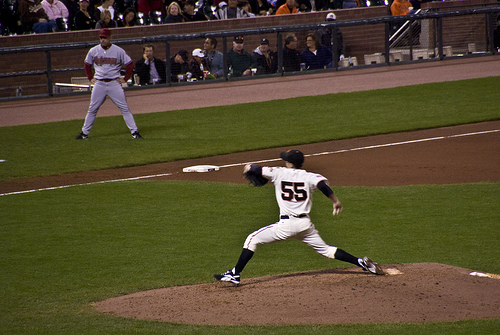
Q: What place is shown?
A: It is a field.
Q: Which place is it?
A: It is a field.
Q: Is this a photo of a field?
A: Yes, it is showing a field.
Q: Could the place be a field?
A: Yes, it is a field.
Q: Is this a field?
A: Yes, it is a field.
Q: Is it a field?
A: Yes, it is a field.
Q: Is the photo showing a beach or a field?
A: It is showing a field.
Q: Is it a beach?
A: No, it is a field.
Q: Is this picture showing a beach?
A: No, the picture is showing a field.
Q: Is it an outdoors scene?
A: Yes, it is outdoors.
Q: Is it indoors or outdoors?
A: It is outdoors.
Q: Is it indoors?
A: No, it is outdoors.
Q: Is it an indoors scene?
A: No, it is outdoors.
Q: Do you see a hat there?
A: Yes, there is a hat.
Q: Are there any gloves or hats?
A: Yes, there is a hat.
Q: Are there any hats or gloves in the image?
A: Yes, there is a hat.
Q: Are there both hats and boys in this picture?
A: No, there is a hat but no boys.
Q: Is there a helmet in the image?
A: No, there are no helmets.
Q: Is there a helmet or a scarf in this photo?
A: No, there are no helmets or scarves.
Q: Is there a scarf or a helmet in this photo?
A: No, there are no helmets or scarves.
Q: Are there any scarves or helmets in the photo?
A: No, there are no helmets or scarves.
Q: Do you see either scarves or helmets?
A: No, there are no helmets or scarves.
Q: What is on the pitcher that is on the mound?
A: The hat is on the pitcher.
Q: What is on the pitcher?
A: The hat is on the pitcher.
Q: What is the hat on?
A: The hat is on the pitcher.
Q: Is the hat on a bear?
A: No, the hat is on the pitcher.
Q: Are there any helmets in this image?
A: No, there are no helmets.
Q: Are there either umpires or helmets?
A: No, there are no helmets or umpires.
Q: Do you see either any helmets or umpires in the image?
A: No, there are no helmets or umpires.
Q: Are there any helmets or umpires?
A: No, there are no helmets or umpires.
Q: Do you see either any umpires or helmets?
A: No, there are no helmets or umpires.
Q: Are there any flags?
A: No, there are no flags.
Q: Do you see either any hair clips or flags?
A: No, there are no flags or hair clips.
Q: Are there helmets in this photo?
A: No, there are no helmets.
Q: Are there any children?
A: No, there are no children.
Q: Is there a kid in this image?
A: No, there are no children.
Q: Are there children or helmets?
A: No, there are no children or helmets.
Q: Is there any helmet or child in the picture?
A: No, there are no children or helmets.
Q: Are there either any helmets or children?
A: No, there are no children or helmets.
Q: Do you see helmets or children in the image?
A: No, there are no children or helmets.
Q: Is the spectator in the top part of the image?
A: Yes, the spectator is in the top of the image.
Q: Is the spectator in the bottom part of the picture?
A: No, the spectator is in the top of the image.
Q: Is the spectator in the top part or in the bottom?
A: The spectator is in the top of the image.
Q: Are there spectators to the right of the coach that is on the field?
A: Yes, there is a spectator to the right of the coach.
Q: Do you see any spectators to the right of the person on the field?
A: Yes, there is a spectator to the right of the coach.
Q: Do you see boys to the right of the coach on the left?
A: No, there is a spectator to the right of the coach.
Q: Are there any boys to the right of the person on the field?
A: No, there is a spectator to the right of the coach.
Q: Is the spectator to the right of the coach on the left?
A: Yes, the spectator is to the right of the coach.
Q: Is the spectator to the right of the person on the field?
A: Yes, the spectator is to the right of the coach.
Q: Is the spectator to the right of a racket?
A: No, the spectator is to the right of the coach.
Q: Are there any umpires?
A: No, there are no umpires.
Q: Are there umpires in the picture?
A: No, there are no umpires.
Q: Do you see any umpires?
A: No, there are no umpires.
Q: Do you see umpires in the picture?
A: No, there are no umpires.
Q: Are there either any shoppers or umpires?
A: No, there are no umpires or shoppers.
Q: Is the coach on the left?
A: Yes, the coach is on the left of the image.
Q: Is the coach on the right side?
A: No, the coach is on the left of the image.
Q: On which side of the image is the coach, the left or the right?
A: The coach is on the left of the image.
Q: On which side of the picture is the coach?
A: The coach is on the left of the image.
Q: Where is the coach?
A: The coach is on the field.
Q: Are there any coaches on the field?
A: Yes, there is a coach on the field.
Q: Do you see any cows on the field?
A: No, there is a coach on the field.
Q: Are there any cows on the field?
A: No, there is a coach on the field.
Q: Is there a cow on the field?
A: No, there is a coach on the field.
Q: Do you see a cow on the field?
A: No, there is a coach on the field.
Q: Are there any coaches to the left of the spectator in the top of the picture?
A: Yes, there is a coach to the left of the spectator.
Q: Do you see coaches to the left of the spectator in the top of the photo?
A: Yes, there is a coach to the left of the spectator.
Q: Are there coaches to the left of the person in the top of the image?
A: Yes, there is a coach to the left of the spectator.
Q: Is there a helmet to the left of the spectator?
A: No, there is a coach to the left of the spectator.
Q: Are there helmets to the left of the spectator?
A: No, there is a coach to the left of the spectator.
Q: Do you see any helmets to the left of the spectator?
A: No, there is a coach to the left of the spectator.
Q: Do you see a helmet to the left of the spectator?
A: No, there is a coach to the left of the spectator.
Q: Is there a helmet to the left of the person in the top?
A: No, there is a coach to the left of the spectator.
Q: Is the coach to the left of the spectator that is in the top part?
A: Yes, the coach is to the left of the spectator.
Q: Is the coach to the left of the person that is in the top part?
A: Yes, the coach is to the left of the spectator.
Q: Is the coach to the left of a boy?
A: No, the coach is to the left of the spectator.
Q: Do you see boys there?
A: No, there are no boys.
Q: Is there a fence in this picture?
A: Yes, there is a fence.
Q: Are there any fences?
A: Yes, there is a fence.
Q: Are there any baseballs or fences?
A: Yes, there is a fence.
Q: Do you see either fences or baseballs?
A: Yes, there is a fence.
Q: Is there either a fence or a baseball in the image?
A: Yes, there is a fence.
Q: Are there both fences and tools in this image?
A: No, there is a fence but no tools.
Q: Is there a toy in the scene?
A: No, there are no toys.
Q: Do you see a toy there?
A: No, there are no toys.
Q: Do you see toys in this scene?
A: No, there are no toys.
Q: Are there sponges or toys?
A: No, there are no toys or sponges.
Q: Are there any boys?
A: No, there are no boys.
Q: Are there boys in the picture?
A: No, there are no boys.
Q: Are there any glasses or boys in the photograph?
A: No, there are no boys or glasses.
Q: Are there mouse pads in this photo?
A: No, there are no mouse pads.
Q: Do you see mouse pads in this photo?
A: No, there are no mouse pads.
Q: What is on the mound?
A: The pitcher is on the mound.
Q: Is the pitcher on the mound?
A: Yes, the pitcher is on the mound.